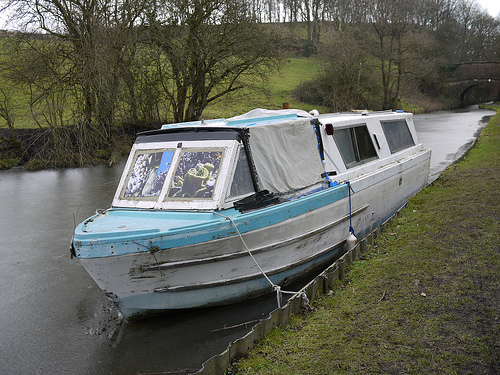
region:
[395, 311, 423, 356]
part of a ground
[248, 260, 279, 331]
part of a rope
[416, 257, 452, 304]
part of a ground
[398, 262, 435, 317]
part of a ground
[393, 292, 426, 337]
part of a grpounmd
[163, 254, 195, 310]
aprt of a line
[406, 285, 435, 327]
part of a ground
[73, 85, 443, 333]
a blue and white boat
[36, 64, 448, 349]
a boat in the water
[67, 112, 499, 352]
a boat tied to shore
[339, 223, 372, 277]
a white bumper on side of boat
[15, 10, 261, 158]
trees without leaves on them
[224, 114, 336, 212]
a gray canvas over the side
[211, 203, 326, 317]
a white rope from the boat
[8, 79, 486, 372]
a narrow river bed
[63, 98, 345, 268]
blue area on boat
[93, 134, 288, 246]
a front window on boat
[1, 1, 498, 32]
light of daytime sky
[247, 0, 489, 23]
leafless trees on horizon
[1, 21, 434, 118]
green grass on hill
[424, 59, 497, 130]
bridge over body of water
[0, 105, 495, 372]
calm water of river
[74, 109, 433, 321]
blue and white boat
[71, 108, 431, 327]
boat docked on river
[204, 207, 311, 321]
rope tied to fence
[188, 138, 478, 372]
metal fence along river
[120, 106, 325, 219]
fabric over boat cabin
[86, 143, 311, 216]
this is a boat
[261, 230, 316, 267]
ther boat is white in color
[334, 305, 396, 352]
this is a grass area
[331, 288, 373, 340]
the grass is green in color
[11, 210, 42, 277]
this is a stream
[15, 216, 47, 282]
the water is calm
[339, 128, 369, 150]
this is a window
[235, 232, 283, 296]
this is a rope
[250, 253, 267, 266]
the rope is white in color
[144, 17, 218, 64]
this is a tree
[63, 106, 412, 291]
this is a boat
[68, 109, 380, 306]
the boat is on the water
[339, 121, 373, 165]
the window is open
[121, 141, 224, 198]
this is the front screen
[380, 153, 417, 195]
the boat is white in color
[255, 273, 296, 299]
this is a rope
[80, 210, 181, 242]
the front is blue in color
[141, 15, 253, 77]
this is the trees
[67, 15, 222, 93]
the trees are dry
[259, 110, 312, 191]
this is a sheet